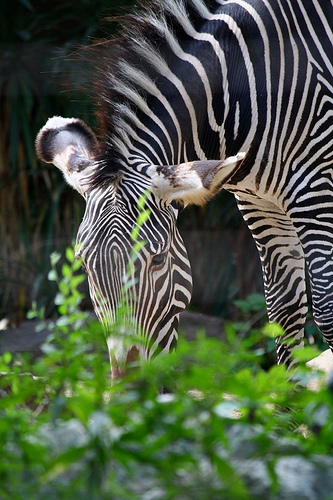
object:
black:
[302, 240, 327, 256]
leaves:
[149, 402, 190, 457]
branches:
[103, 392, 308, 500]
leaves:
[89, 422, 161, 475]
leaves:
[170, 373, 251, 427]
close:
[138, 402, 207, 500]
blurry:
[27, 403, 95, 500]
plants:
[35, 366, 328, 471]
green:
[55, 476, 104, 500]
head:
[73, 183, 194, 407]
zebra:
[244, 157, 309, 206]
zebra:
[149, 46, 255, 88]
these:
[52, 339, 105, 457]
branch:
[67, 445, 161, 500]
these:
[139, 468, 186, 500]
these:
[166, 336, 254, 409]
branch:
[157, 375, 250, 465]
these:
[99, 444, 281, 496]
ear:
[141, 145, 248, 200]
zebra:
[281, 83, 313, 116]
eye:
[146, 246, 172, 279]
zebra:
[282, 215, 315, 235]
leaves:
[154, 341, 239, 438]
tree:
[214, 430, 309, 482]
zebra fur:
[191, 36, 301, 144]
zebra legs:
[237, 174, 317, 364]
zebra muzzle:
[97, 340, 161, 378]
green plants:
[59, 348, 105, 421]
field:
[3, 302, 320, 495]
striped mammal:
[32, 4, 319, 388]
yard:
[3, 319, 314, 496]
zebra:
[21, 2, 331, 430]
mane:
[84, 2, 225, 159]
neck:
[115, 18, 275, 219]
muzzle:
[108, 322, 175, 414]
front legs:
[222, 175, 331, 357]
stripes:
[152, 4, 276, 152]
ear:
[40, 101, 107, 198]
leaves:
[0, 338, 246, 452]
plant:
[12, 186, 316, 489]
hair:
[70, 30, 160, 161]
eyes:
[74, 248, 170, 269]